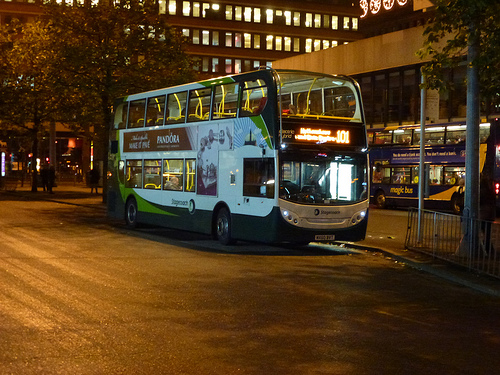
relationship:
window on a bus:
[184, 156, 196, 193] [111, 71, 368, 246]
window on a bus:
[161, 157, 183, 189] [111, 71, 368, 246]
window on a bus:
[141, 158, 161, 188] [111, 71, 368, 246]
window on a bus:
[208, 80, 238, 116] [111, 71, 368, 246]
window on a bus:
[123, 157, 142, 188] [111, 71, 368, 246]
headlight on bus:
[270, 199, 298, 236] [105, 64, 352, 251]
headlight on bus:
[340, 203, 375, 233] [105, 64, 352, 251]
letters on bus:
[294, 124, 354, 145] [254, 75, 446, 221]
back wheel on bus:
[120, 191, 142, 226] [88, 60, 394, 266]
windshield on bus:
[282, 155, 362, 199] [111, 71, 368, 246]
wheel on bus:
[195, 199, 253, 254] [111, 71, 368, 246]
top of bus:
[119, 72, 348, 140] [111, 71, 368, 246]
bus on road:
[91, 65, 376, 246] [1, 197, 497, 368]